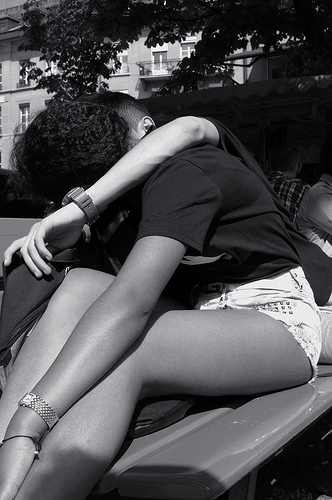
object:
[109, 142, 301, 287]
shirt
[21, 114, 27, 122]
window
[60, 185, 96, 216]
watch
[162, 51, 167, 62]
window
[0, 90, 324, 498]
person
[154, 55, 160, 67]
window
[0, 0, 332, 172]
building